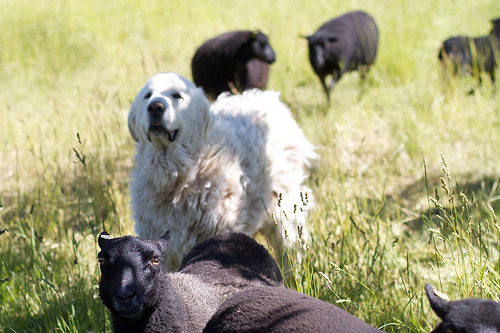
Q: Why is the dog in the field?
A: He is guarding the sheep.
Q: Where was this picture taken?
A: In a field.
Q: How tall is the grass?
A: As tall as half the height of the dog.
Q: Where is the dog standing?
A: In the shade.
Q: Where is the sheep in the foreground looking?
A: Towards the camera.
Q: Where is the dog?
A: In the grass.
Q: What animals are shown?
A: Dog and sheep.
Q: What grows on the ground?
A: Grass.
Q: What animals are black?
A: Sheep.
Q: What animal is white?
A: Dog.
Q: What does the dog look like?
A: Fluffy.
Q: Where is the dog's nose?
A: On its face.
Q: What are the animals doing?
A: Standing.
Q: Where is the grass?
A: On the ground.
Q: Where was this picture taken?
A: A field.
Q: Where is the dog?
A: In the grass.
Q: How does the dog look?
A: Fluffy.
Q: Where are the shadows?
A: On the dog and the ground.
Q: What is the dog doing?
A: Herding sheep.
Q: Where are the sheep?
A: In the grass.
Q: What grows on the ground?
A: Grass.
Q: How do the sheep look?
A: Black.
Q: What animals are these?
A: Dog and sheep.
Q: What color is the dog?
A: White.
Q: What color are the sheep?
A: Black.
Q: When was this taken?
A: During the day.